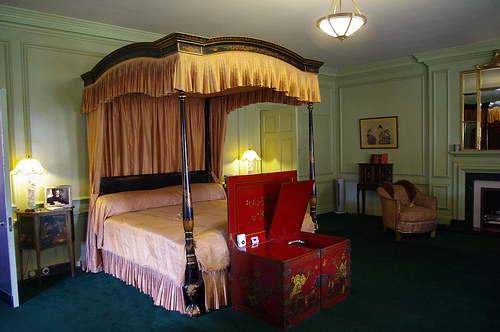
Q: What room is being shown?
A: Bedroom.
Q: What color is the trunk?
A: Red.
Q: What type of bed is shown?
A: Canopy bed.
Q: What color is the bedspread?
A: Pink.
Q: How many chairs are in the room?
A: 1.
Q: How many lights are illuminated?
A: 3.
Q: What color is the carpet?
A: Blue.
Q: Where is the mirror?
A: Above the fireplace.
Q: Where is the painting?
A: On the wall.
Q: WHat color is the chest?
A: Red.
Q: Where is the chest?
A: In front of the bed.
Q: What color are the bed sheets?
A: Pink.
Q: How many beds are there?
A: One.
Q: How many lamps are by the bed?
A: Two.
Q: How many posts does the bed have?
A: Four.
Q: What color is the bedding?
A: Pink.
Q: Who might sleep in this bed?
A: A girl.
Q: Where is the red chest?
A: At the foot of the bed.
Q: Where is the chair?
A: By the fireplace.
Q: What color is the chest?
A: Red.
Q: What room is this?
A: The bedroom.